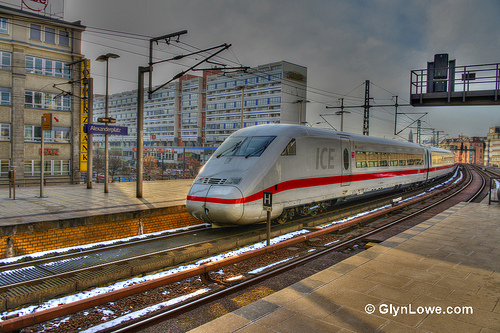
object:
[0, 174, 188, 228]
platform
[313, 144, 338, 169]
"ice"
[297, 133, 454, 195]
side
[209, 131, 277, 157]
winshield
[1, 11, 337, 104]
power lines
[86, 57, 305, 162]
buildings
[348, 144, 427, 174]
windows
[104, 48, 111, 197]
light pole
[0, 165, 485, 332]
tracks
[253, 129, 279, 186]
ground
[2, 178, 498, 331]
ground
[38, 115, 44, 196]
pole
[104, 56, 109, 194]
pole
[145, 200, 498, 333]
sidewalk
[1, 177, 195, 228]
sidewalk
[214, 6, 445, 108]
clouds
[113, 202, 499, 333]
platform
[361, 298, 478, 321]
web address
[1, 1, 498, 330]
photo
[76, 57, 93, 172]
sign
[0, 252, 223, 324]
snow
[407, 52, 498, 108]
platform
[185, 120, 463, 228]
train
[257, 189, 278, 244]
sign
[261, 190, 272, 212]
letter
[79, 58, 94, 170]
lettering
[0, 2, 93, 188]
building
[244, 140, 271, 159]
wipers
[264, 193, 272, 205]
h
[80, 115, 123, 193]
sign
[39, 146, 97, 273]
travelers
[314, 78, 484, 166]
distance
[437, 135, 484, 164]
building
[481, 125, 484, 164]
building